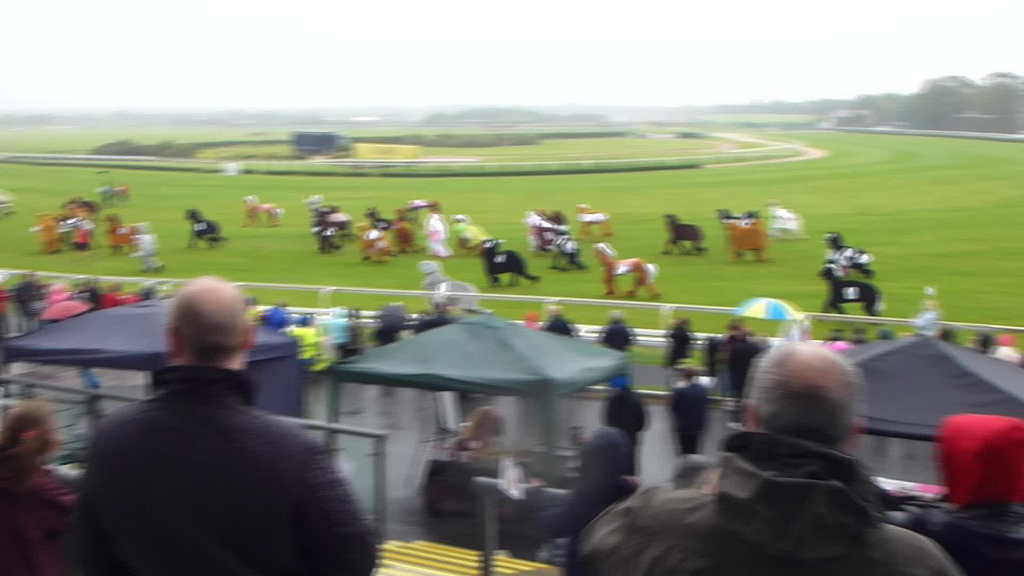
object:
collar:
[151, 364, 258, 405]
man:
[76, 274, 378, 576]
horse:
[239, 195, 282, 227]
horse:
[354, 221, 397, 262]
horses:
[32, 180, 883, 317]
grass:
[0, 128, 1024, 352]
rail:
[269, 416, 389, 542]